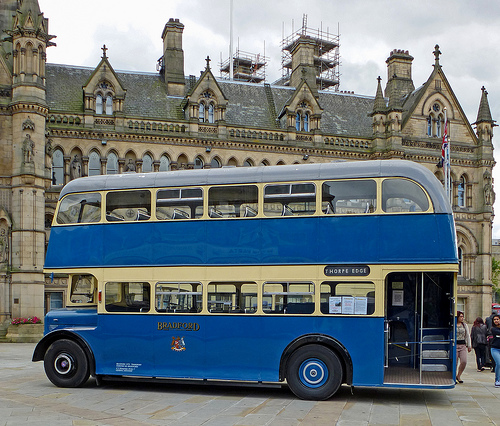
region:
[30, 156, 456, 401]
blue and yellow double decker bus on a street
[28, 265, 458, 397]
the lower level of a double decker bus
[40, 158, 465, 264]
the upper level of a double decker bus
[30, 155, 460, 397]
yellow and blue bus on a street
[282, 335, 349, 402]
black wheel of a double decker bus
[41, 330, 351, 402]
two black wheels of a bus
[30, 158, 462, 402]
bus on a street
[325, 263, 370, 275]
black sign on a bus with white text print on it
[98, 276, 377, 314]
row of windows on the lower level of a bus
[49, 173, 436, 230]
row of windows on the upper level of a bus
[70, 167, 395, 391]
blue and yellow double decker bus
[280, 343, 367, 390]
bus has blue and white hubcaps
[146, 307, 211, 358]
logo on bottom half of bus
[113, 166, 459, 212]
grey cap on top of bus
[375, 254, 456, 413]
grey steps to enter bus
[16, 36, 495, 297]
large brown and grey building behind bus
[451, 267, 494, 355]
people are walking around to bus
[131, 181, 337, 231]
white window frames on bus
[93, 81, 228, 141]
white curtains inside building windows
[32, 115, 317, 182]
rows of arched windows behind bus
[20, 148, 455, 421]
A double decker bus.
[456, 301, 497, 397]
People walking near the bus.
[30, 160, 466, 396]
The bus is blue, yellow, and grey.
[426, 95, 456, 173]
A British flag in the background.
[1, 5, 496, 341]
The old building is biege colored.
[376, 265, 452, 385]
A door on the bus.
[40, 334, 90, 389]
The front wheel on the bus.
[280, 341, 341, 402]
The back wheel on the bus.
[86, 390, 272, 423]
Stone slabs on the ground.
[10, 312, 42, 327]
Flowers growing in a planter box.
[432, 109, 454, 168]
Flag hanging on a pole.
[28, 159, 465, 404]
Blue double decker bus.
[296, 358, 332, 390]
Blue rims of double decker bus.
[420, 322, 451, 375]
Steps on double decker bus.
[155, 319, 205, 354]
Logo of bus on outside lower level.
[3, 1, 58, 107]
Spire on left side of building.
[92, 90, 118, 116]
Two windows in building.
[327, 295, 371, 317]
Papers attached to bus window.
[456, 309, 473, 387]
Woman walking behind bus.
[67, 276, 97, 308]
Drivers side window in front of bus.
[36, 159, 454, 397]
a city tour bus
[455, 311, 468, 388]
a girl next to the bus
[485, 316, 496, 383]
a girl in a blue jeans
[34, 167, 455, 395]
a double decker bus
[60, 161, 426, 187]
the roof of the bus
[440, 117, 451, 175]
the UK flag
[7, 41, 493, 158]
an old style building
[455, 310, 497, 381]
three girls walking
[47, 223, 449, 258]
blue side of the bus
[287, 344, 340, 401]
a wheel eith the center white and blue